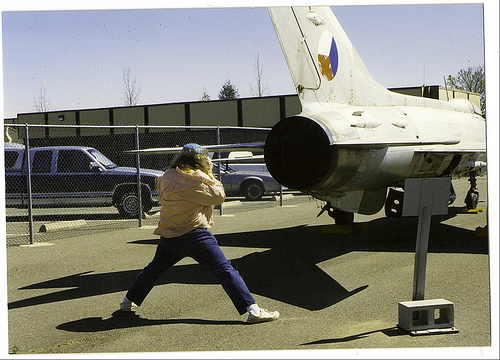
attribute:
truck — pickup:
[1, 145, 190, 224]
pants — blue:
[125, 221, 259, 317]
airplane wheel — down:
[461, 188, 482, 212]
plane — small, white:
[107, 4, 488, 225]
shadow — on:
[270, 220, 358, 312]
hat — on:
[181, 140, 210, 156]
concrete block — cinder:
[393, 288, 458, 345]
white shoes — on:
[240, 303, 284, 330]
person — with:
[126, 137, 283, 327]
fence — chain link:
[7, 120, 307, 247]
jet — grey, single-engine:
[263, 8, 488, 226]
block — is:
[394, 297, 458, 340]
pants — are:
[143, 237, 255, 315]